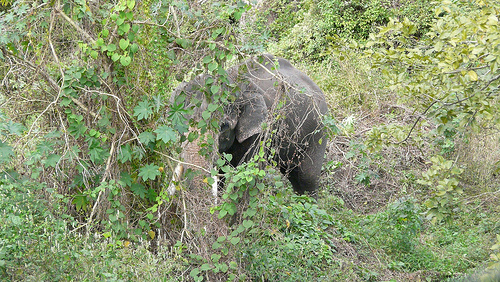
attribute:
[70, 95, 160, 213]
leaves — green 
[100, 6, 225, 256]
branch — tree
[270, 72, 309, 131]
skin — grey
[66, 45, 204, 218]
bushes — dense